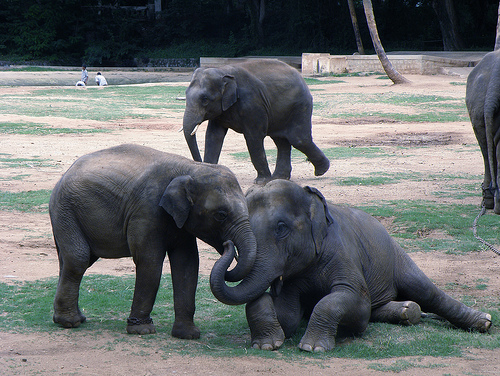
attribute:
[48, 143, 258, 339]
elephant — baby, gray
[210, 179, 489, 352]
elephant — gray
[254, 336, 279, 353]
nails — elephant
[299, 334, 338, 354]
nails — elephant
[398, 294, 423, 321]
nails — elephant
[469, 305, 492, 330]
nails — elephant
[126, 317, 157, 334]
nails — elephant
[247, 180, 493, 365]
elephant — grey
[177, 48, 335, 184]
elephant — gray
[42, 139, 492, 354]
elephants — young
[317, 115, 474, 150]
patch — brown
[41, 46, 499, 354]
elephants — gray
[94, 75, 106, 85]
shirt — white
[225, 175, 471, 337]
elephant — laying down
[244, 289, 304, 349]
leg — grey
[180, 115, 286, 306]
trunks — long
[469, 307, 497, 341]
elephant foot — grey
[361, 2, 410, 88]
trunk — palm, curved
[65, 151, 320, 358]
elephant — grey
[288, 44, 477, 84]
wall — small and stone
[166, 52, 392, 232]
elephants — grey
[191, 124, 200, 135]
tusk — small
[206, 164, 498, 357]
elephant — grey